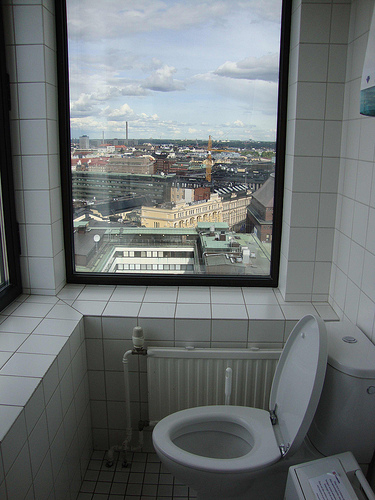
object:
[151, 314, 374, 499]
toilet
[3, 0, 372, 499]
bathroom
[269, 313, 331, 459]
lid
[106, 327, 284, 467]
radiator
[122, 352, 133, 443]
pipe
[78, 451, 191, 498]
tile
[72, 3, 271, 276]
window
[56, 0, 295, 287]
frame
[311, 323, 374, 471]
tank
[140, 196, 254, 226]
building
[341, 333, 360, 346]
flush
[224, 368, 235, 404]
brush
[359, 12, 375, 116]
air refreshener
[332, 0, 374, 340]
wall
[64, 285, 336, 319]
sill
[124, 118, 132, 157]
building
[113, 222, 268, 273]
roof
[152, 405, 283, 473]
seat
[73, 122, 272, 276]
city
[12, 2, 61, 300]
wall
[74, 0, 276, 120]
sky